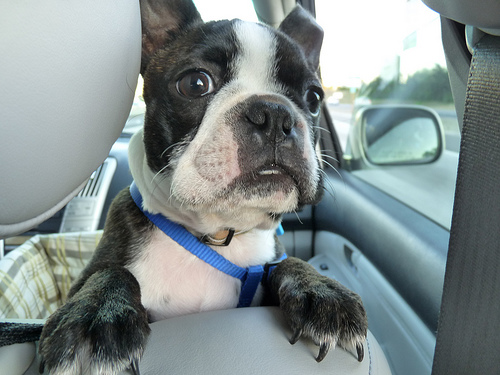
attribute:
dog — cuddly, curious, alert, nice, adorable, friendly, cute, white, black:
[34, 1, 384, 374]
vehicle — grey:
[1, 2, 496, 372]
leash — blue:
[124, 178, 290, 305]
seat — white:
[1, 312, 387, 375]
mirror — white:
[344, 104, 452, 172]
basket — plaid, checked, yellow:
[1, 230, 112, 329]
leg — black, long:
[42, 265, 151, 374]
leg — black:
[269, 255, 375, 362]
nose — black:
[236, 90, 303, 141]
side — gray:
[293, 4, 499, 298]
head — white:
[113, 2, 335, 305]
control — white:
[66, 196, 99, 236]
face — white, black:
[144, 21, 328, 224]